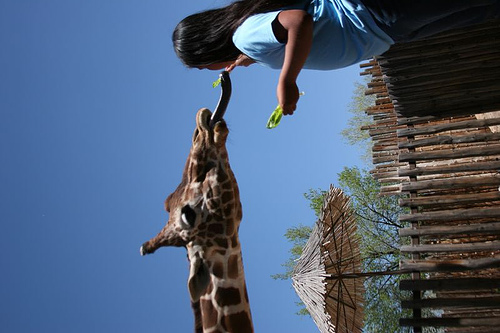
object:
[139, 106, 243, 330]
giraffe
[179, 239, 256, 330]
neck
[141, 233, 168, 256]
horns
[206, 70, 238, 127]
tongue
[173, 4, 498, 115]
girl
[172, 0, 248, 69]
hair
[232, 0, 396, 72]
shirt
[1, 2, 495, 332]
photo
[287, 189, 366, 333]
straw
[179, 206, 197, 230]
eye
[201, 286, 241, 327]
spots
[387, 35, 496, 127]
shade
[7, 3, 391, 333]
sky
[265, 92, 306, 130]
lettuce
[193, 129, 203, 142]
nose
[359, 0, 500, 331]
area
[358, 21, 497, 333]
wood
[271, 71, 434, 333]
tree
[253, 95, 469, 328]
distance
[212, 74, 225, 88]
food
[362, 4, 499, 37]
pants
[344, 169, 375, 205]
leaves